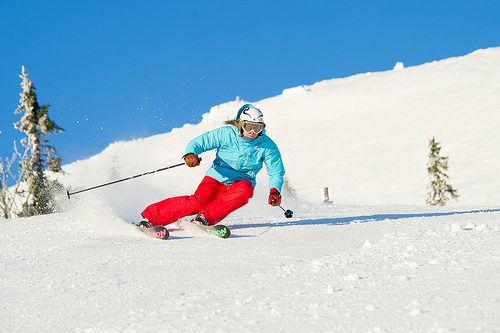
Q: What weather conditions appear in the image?
A: It is cloudless.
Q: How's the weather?
A: It is cloudless.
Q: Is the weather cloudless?
A: Yes, it is cloudless.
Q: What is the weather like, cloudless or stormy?
A: It is cloudless.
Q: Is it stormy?
A: No, it is cloudless.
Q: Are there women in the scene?
A: Yes, there is a woman.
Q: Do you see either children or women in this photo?
A: Yes, there is a woman.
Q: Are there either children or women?
A: Yes, there is a woman.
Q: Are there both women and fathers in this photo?
A: No, there is a woman but no fathers.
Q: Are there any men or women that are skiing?
A: Yes, the woman is skiing.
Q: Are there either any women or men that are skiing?
A: Yes, the woman is skiing.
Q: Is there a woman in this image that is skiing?
A: Yes, there is a woman that is skiing.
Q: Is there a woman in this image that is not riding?
A: Yes, there is a woman that is skiing.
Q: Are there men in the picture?
A: No, there are no men.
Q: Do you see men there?
A: No, there are no men.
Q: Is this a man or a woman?
A: This is a woman.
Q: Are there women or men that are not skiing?
A: No, there is a woman but she is skiing.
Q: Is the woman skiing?
A: Yes, the woman is skiing.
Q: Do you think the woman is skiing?
A: Yes, the woman is skiing.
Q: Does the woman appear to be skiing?
A: Yes, the woman is skiing.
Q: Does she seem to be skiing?
A: Yes, the woman is skiing.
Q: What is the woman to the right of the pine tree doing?
A: The woman is skiing.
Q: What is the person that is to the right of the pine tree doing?
A: The woman is skiing.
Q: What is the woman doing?
A: The woman is skiing.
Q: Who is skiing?
A: The woman is skiing.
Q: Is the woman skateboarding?
A: No, the woman is skiing.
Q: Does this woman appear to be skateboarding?
A: No, the woman is skiing.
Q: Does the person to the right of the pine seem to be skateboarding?
A: No, the woman is skiing.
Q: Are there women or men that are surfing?
A: No, there is a woman but she is skiing.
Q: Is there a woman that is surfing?
A: No, there is a woman but she is skiing.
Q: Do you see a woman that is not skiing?
A: No, there is a woman but she is skiing.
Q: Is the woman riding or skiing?
A: The woman is skiing.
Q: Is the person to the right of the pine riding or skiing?
A: The woman is skiing.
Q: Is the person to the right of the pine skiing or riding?
A: The woman is skiing.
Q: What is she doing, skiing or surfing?
A: The woman is skiing.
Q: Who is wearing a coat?
A: The woman is wearing a coat.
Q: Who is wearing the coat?
A: The woman is wearing a coat.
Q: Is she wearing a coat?
A: Yes, the woman is wearing a coat.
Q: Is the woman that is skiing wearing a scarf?
A: No, the woman is wearing a coat.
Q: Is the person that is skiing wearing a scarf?
A: No, the woman is wearing a coat.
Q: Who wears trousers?
A: The woman wears trousers.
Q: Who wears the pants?
A: The woman wears trousers.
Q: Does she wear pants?
A: Yes, the woman wears pants.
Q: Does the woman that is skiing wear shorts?
A: No, the woman wears pants.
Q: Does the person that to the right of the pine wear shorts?
A: No, the woman wears pants.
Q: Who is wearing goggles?
A: The woman is wearing goggles.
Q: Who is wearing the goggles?
A: The woman is wearing goggles.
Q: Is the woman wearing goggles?
A: Yes, the woman is wearing goggles.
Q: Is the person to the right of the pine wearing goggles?
A: Yes, the woman is wearing goggles.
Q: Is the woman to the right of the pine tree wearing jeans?
A: No, the woman is wearing goggles.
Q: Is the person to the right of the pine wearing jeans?
A: No, the woman is wearing goggles.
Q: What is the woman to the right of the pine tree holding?
A: The woman is holding the pole.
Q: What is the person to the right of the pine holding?
A: The woman is holding the pole.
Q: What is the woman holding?
A: The woman is holding the pole.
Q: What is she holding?
A: The woman is holding the pole.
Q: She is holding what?
A: The woman is holding the pole.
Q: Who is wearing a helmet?
A: The woman is wearing a helmet.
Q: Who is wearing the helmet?
A: The woman is wearing a helmet.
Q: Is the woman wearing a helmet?
A: Yes, the woman is wearing a helmet.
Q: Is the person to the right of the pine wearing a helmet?
A: Yes, the woman is wearing a helmet.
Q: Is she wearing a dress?
A: No, the woman is wearing a helmet.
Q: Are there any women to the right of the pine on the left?
A: Yes, there is a woman to the right of the pine.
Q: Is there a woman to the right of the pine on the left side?
A: Yes, there is a woman to the right of the pine.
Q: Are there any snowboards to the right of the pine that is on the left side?
A: No, there is a woman to the right of the pine tree.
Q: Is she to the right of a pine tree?
A: Yes, the woman is to the right of a pine tree.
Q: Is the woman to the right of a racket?
A: No, the woman is to the right of a pine tree.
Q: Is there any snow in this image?
A: Yes, there is snow.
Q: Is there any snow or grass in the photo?
A: Yes, there is snow.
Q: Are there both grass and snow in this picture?
A: No, there is snow but no grass.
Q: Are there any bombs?
A: No, there are no bombs.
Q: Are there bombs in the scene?
A: No, there are no bombs.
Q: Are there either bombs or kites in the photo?
A: No, there are no bombs or kites.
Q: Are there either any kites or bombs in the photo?
A: No, there are no bombs or kites.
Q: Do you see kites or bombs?
A: No, there are no bombs or kites.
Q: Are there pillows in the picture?
A: No, there are no pillows.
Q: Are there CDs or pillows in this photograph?
A: No, there are no pillows or cds.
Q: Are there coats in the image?
A: Yes, there is a coat.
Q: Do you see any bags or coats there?
A: Yes, there is a coat.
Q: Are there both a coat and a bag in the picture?
A: No, there is a coat but no bags.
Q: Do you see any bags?
A: No, there are no bags.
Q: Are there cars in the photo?
A: No, there are no cars.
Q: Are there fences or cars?
A: No, there are no cars or fences.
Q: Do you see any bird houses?
A: No, there are no bird houses.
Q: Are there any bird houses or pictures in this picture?
A: No, there are no bird houses or pictures.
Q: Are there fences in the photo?
A: No, there are no fences.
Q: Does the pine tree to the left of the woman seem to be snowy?
A: Yes, the pine tree is snowy.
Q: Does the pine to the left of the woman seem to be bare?
A: No, the pine is snowy.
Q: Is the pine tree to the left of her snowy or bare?
A: The pine is snowy.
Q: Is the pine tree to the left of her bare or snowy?
A: The pine is snowy.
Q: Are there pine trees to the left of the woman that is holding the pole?
A: Yes, there is a pine tree to the left of the woman.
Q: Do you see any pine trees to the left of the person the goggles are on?
A: Yes, there is a pine tree to the left of the woman.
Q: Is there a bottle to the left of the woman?
A: No, there is a pine tree to the left of the woman.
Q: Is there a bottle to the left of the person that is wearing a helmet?
A: No, there is a pine tree to the left of the woman.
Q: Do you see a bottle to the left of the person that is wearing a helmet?
A: No, there is a pine tree to the left of the woman.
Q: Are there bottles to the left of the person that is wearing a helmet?
A: No, there is a pine tree to the left of the woman.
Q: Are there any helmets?
A: Yes, there is a helmet.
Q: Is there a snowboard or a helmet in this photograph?
A: Yes, there is a helmet.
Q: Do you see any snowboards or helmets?
A: Yes, there is a helmet.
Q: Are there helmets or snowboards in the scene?
A: Yes, there is a helmet.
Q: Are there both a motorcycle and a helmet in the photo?
A: No, there is a helmet but no motorcycles.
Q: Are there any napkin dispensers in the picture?
A: No, there are no napkin dispensers.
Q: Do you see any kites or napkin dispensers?
A: No, there are no napkin dispensers or kites.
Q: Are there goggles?
A: Yes, there are goggles.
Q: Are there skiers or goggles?
A: Yes, there are goggles.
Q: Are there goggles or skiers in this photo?
A: Yes, there are goggles.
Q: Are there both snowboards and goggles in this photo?
A: No, there are goggles but no snowboards.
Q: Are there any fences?
A: No, there are no fences.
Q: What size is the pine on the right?
A: The pine is small.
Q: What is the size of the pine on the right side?
A: The pine is small.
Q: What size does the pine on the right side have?
A: The pine has small size.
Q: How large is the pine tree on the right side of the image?
A: The pine is small.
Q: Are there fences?
A: No, there are no fences.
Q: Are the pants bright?
A: Yes, the pants are bright.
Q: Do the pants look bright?
A: Yes, the pants are bright.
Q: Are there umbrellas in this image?
A: No, there are no umbrellas.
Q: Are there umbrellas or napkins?
A: No, there are no umbrellas or napkins.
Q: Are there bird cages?
A: No, there are no bird cages.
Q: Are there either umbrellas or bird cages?
A: No, there are no bird cages or umbrellas.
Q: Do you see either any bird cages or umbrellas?
A: No, there are no bird cages or umbrellas.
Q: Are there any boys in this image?
A: No, there are no boys.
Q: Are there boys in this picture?
A: No, there are no boys.